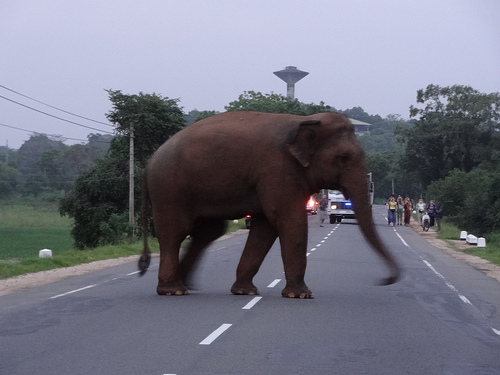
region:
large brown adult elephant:
[131, 92, 398, 304]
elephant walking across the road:
[131, 94, 402, 316]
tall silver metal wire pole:
[122, 113, 137, 233]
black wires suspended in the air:
[0, 75, 115, 166]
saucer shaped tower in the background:
[273, 55, 307, 96]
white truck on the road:
[331, 188, 347, 222]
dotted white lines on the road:
[197, 317, 239, 350]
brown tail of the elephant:
[133, 187, 148, 279]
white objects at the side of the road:
[459, 223, 489, 253]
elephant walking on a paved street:
[5, 2, 495, 367]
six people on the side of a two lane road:
[383, 192, 444, 231]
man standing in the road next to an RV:
[314, 183, 371, 230]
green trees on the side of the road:
[401, 79, 497, 239]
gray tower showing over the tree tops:
[273, 63, 308, 108]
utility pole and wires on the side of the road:
[0, 77, 140, 234]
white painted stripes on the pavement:
[205, 221, 340, 346]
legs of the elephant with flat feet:
[152, 199, 315, 301]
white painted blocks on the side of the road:
[455, 226, 490, 251]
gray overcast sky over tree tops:
[1, 3, 493, 141]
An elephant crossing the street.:
[104, 102, 414, 347]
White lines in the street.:
[205, 278, 256, 363]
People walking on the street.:
[382, 195, 440, 245]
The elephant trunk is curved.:
[348, 180, 418, 305]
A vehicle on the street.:
[330, 176, 371, 224]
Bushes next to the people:
[425, 138, 480, 236]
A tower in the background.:
[255, 56, 325, 102]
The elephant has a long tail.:
[128, 175, 153, 272]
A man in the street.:
[315, 188, 325, 238]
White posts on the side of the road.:
[453, 215, 497, 262]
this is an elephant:
[37, 33, 450, 373]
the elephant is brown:
[120, 111, 377, 316]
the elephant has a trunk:
[134, 113, 365, 325]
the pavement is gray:
[99, 313, 166, 374]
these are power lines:
[30, 83, 109, 162]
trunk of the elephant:
[349, 192, 399, 284]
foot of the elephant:
[277, 283, 317, 304]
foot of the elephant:
[225, 280, 265, 297]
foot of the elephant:
[190, 273, 202, 290]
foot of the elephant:
[147, 279, 187, 299]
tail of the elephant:
[133, 223, 152, 273]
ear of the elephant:
[285, 114, 322, 172]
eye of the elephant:
[314, 143, 364, 169]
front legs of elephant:
[222, 272, 308, 303]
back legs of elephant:
[150, 273, 201, 294]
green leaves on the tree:
[440, 112, 477, 164]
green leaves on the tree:
[462, 158, 488, 210]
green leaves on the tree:
[410, 96, 449, 151]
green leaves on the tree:
[82, 175, 132, 237]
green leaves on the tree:
[124, 97, 160, 138]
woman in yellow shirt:
[386, 192, 397, 224]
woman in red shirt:
[400, 196, 410, 228]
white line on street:
[193, 317, 239, 351]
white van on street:
[319, 157, 376, 234]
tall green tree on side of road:
[63, 84, 193, 259]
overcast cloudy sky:
[2, 7, 497, 156]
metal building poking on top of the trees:
[271, 57, 311, 103]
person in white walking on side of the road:
[409, 198, 426, 227]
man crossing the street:
[316, 192, 331, 229]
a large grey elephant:
[138, 104, 400, 299]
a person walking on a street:
[386, 195, 398, 222]